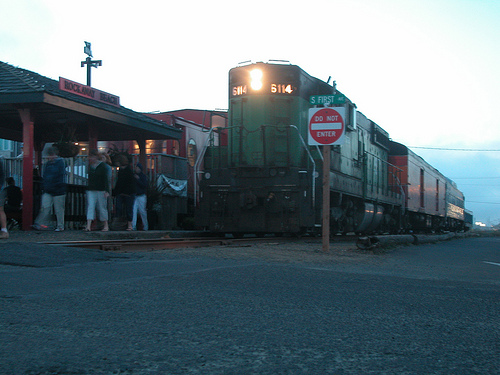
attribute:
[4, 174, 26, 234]
person — sitting, waiting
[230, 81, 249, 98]
number — 6114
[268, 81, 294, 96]
number — 6114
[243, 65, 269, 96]
light — on, bright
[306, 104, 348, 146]
sign — warning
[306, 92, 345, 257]
street sign — crossroad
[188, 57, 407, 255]
car — green, first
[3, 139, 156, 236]
people — blurry, waiting, tired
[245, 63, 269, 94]
lights — on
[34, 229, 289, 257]
train tracks — red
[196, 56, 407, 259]
train car — 6114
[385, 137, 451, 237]
train car — red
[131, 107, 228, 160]
building — red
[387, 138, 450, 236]
car — second, red